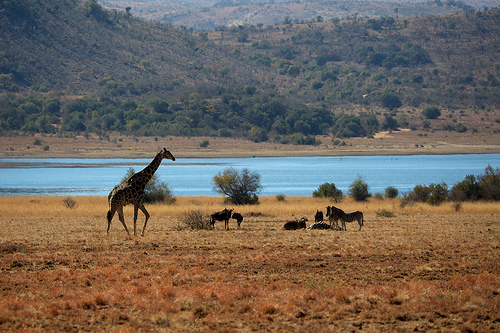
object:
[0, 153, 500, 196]
water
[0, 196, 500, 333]
ground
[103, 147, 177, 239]
giraffe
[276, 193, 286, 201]
bush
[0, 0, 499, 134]
hill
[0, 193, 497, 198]
horizon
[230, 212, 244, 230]
animal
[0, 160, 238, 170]
wave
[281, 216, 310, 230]
animal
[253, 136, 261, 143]
tree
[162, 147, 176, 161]
head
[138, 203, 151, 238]
leg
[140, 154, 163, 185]
neck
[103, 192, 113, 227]
tail